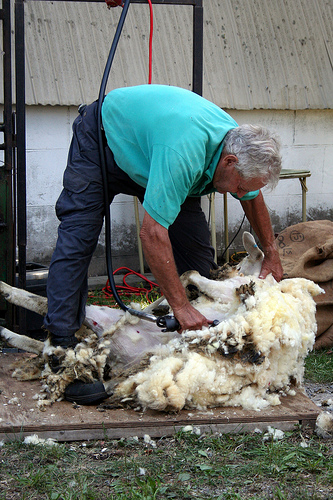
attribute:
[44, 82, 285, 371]
man — shearing, sheering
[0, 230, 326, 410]
sheep — white, sheared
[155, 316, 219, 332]
clippers — electric, black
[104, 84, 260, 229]
shirt — green, blue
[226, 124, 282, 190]
hair — gray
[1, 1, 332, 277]
building — cement, white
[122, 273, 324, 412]
wool — cut, yellow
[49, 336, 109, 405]
boot — black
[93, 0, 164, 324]
chord — red, long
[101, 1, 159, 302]
chord — red, hanging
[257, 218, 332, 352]
bag — brown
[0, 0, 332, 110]
roof — metal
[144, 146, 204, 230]
sleeve — short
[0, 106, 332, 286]
wall — worn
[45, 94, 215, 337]
pants — blue